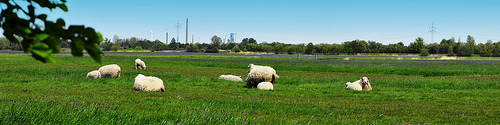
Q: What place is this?
A: It is a field.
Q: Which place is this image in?
A: It is at the field.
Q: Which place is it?
A: It is a field.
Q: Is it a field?
A: Yes, it is a field.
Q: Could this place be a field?
A: Yes, it is a field.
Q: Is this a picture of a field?
A: Yes, it is showing a field.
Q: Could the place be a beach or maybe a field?
A: It is a field.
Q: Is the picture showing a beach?
A: No, the picture is showing a field.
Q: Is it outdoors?
A: Yes, it is outdoors.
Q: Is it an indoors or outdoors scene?
A: It is outdoors.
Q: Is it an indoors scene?
A: No, it is outdoors.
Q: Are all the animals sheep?
A: Yes, all the animals are sheep.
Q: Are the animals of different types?
A: No, all the animals are sheep.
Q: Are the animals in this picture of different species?
A: No, all the animals are sheep.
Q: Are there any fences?
A: No, there are no fences.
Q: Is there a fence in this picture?
A: No, there are no fences.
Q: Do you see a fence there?
A: No, there are no fences.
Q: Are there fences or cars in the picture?
A: No, there are no fences or cars.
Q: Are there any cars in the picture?
A: No, there are no cars.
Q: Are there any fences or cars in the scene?
A: No, there are no cars or fences.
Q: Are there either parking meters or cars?
A: No, there are no cars or parking meters.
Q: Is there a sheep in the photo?
A: Yes, there is a sheep.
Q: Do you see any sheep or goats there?
A: Yes, there is a sheep.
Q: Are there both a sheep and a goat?
A: No, there is a sheep but no goats.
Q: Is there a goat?
A: No, there are no goats.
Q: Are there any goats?
A: No, there are no goats.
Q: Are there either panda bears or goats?
A: No, there are no goats or panda bears.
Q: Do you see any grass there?
A: Yes, there is grass.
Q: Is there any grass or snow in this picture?
A: Yes, there is grass.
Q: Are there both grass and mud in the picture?
A: No, there is grass but no mud.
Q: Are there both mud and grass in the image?
A: No, there is grass but no mud.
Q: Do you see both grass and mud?
A: No, there is grass but no mud.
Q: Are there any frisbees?
A: No, there are no frisbees.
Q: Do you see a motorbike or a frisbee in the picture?
A: No, there are no frisbees or motorcycles.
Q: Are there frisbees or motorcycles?
A: No, there are no frisbees or motorcycles.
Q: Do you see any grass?
A: Yes, there is grass.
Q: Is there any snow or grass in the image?
A: Yes, there is grass.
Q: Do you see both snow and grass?
A: No, there is grass but no snow.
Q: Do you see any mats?
A: No, there are no mats.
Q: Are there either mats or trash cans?
A: No, there are no mats or trash cans.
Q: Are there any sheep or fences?
A: Yes, there is a sheep.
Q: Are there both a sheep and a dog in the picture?
A: No, there is a sheep but no dogs.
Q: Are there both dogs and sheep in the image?
A: No, there is a sheep but no dogs.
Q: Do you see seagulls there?
A: No, there are no seagulls.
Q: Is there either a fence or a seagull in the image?
A: No, there are no seagulls or fences.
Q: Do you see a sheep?
A: Yes, there is a sheep.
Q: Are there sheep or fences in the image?
A: Yes, there is a sheep.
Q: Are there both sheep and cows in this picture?
A: No, there is a sheep but no cows.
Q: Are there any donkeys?
A: No, there are no donkeys.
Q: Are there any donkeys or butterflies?
A: No, there are no donkeys or butterflies.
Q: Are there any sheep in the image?
A: Yes, there is a sheep.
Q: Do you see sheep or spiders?
A: Yes, there is a sheep.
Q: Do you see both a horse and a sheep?
A: No, there is a sheep but no horses.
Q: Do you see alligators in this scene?
A: No, there are no alligators.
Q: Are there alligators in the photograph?
A: No, there are no alligators.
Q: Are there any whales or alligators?
A: No, there are no alligators or whales.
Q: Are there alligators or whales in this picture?
A: No, there are no alligators or whales.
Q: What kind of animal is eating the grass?
A: The animal is a sheep.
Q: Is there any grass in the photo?
A: Yes, there is grass.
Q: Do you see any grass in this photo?
A: Yes, there is grass.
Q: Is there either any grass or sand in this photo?
A: Yes, there is grass.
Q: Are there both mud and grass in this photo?
A: No, there is grass but no mud.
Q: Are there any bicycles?
A: No, there are no bicycles.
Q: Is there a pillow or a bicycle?
A: No, there are no bicycles or pillows.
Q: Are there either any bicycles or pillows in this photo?
A: No, there are no bicycles or pillows.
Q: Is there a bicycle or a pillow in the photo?
A: No, there are no bicycles or pillows.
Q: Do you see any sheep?
A: Yes, there is a sheep.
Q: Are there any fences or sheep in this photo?
A: Yes, there is a sheep.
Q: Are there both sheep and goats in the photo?
A: No, there is a sheep but no goats.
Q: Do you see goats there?
A: No, there are no goats.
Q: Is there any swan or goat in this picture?
A: No, there are no goats or swans.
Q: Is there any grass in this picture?
A: Yes, there is grass.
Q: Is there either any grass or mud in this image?
A: Yes, there is grass.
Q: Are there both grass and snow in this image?
A: No, there is grass but no snow.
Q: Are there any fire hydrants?
A: No, there are no fire hydrants.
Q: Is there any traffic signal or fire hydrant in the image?
A: No, there are no fire hydrants or traffic lights.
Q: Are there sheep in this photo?
A: Yes, there is a sheep.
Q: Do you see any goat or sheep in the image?
A: Yes, there is a sheep.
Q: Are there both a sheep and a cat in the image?
A: No, there is a sheep but no cats.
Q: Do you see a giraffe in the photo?
A: No, there are no giraffes.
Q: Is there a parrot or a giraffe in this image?
A: No, there are no giraffes or parrots.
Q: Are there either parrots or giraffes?
A: No, there are no giraffes or parrots.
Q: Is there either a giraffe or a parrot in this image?
A: No, there are no giraffes or parrots.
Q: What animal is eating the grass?
A: The sheep is eating the grass.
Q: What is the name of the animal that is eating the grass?
A: The animal is a sheep.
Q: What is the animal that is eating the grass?
A: The animal is a sheep.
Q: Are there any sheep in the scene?
A: Yes, there is a sheep.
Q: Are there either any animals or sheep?
A: Yes, there is a sheep.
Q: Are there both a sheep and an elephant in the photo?
A: No, there is a sheep but no elephants.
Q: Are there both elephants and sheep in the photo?
A: No, there is a sheep but no elephants.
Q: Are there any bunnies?
A: No, there are no bunnies.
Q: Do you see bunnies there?
A: No, there are no bunnies.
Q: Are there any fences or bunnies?
A: No, there are no bunnies or fences.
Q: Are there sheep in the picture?
A: Yes, there is a sheep.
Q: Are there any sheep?
A: Yes, there is a sheep.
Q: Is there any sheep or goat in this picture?
A: Yes, there is a sheep.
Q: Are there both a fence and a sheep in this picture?
A: No, there is a sheep but no fences.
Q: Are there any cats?
A: No, there are no cats.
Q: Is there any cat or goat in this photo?
A: No, there are no cats or goats.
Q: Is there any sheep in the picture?
A: Yes, there is a sheep.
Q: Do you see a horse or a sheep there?
A: Yes, there is a sheep.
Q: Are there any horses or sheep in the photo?
A: Yes, there is a sheep.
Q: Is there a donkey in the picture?
A: No, there are no donkeys.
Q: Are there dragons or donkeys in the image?
A: No, there are no donkeys or dragons.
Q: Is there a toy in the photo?
A: No, there are no toys.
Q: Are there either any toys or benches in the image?
A: No, there are no toys or benches.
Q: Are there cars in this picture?
A: No, there are no cars.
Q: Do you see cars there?
A: No, there are no cars.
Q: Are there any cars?
A: No, there are no cars.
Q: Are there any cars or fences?
A: No, there are no cars or fences.